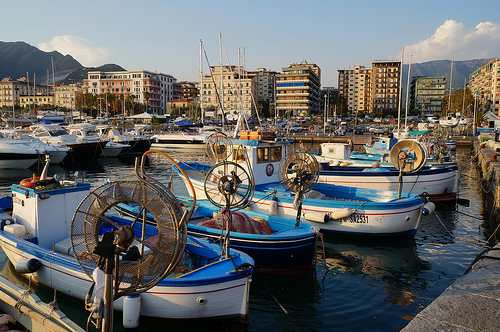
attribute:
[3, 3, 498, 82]
sky — blue, white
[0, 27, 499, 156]
masts — tall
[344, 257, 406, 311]
water — grey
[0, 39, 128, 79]
mountain — green, distant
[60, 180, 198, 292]
fan — black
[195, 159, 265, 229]
fan — black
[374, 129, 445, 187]
fan — black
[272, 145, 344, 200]
fan — black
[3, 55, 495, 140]
buildings — brown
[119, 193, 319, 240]
bed — blue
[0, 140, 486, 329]
water — dark blue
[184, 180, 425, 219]
stripe — red